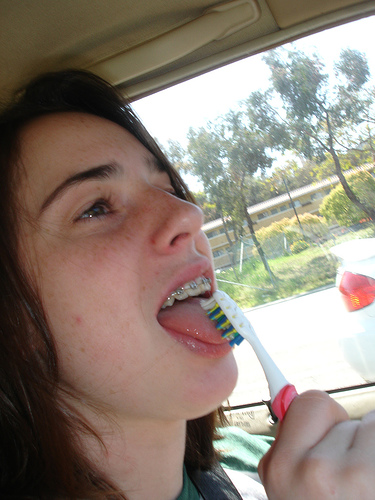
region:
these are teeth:
[143, 254, 225, 310]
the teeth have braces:
[146, 268, 226, 311]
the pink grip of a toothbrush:
[266, 371, 298, 421]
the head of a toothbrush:
[195, 285, 260, 357]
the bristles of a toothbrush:
[197, 295, 248, 350]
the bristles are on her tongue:
[197, 293, 245, 348]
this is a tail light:
[336, 268, 374, 312]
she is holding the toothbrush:
[0, 93, 373, 494]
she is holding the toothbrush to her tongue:
[8, 46, 370, 498]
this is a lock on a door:
[257, 391, 281, 430]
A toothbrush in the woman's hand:
[202, 293, 372, 499]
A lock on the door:
[264, 395, 274, 421]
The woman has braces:
[161, 275, 209, 308]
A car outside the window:
[329, 238, 373, 386]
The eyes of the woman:
[72, 186, 178, 224]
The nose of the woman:
[143, 187, 205, 252]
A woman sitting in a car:
[0, 70, 373, 499]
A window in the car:
[121, 13, 373, 408]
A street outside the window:
[224, 287, 356, 409]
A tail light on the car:
[340, 269, 373, 314]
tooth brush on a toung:
[195, 291, 259, 356]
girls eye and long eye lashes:
[57, 185, 130, 233]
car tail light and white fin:
[313, 215, 372, 354]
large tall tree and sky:
[239, 43, 357, 167]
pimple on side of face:
[58, 290, 99, 337]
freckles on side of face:
[76, 232, 140, 262]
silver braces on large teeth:
[165, 278, 214, 299]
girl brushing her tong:
[52, 143, 258, 379]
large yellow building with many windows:
[211, 187, 345, 258]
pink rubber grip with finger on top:
[251, 318, 314, 424]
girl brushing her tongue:
[1, 50, 373, 498]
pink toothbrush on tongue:
[197, 286, 303, 424]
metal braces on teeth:
[153, 271, 217, 303]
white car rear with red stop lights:
[325, 231, 373, 397]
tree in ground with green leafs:
[202, 127, 282, 276]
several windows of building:
[261, 197, 294, 222]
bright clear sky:
[180, 85, 216, 110]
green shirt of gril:
[181, 422, 281, 498]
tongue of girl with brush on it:
[160, 291, 224, 348]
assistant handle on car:
[91, 0, 266, 97]